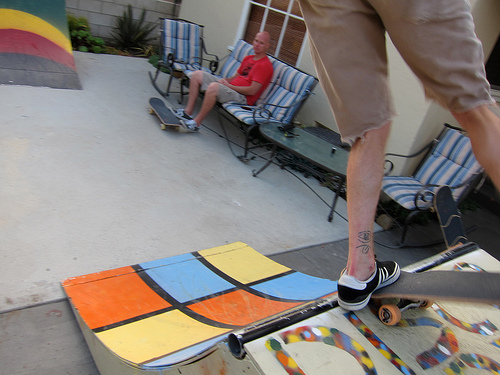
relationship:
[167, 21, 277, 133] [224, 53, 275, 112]
man wearing shirt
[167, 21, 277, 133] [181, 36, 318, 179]
man on couch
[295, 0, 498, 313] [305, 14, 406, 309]
man has leg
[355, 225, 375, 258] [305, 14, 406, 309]
tattoo on leg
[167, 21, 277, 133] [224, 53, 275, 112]
man in shirt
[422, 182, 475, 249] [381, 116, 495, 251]
skateboard leaning against chair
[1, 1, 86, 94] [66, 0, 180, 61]
skateboard ramp against wall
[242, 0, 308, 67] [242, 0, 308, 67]
window with window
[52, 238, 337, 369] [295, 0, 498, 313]
skateboard ramp under man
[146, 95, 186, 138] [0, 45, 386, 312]
skateboard on concrete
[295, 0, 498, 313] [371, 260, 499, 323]
man on skateboard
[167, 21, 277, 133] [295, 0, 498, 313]
man watching man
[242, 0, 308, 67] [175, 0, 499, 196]
window on wall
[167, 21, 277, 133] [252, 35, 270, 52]
man has face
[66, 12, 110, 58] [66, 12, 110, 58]
plant has plant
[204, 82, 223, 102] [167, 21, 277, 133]
knee of man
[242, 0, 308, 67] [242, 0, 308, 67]
window of window